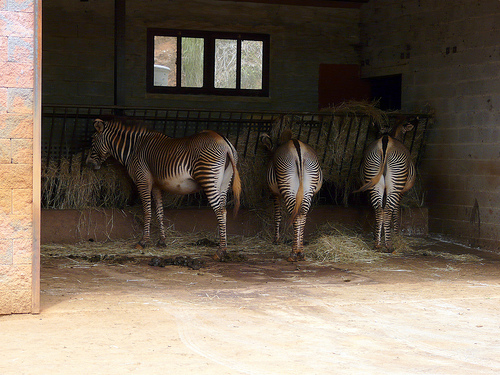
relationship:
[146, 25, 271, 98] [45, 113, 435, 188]
window over feeder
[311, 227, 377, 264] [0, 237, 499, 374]
hay on ground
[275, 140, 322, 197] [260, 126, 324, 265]
hind of zebra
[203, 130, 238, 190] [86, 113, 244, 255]
hind of zebra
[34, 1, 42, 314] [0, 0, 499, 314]
trim on wall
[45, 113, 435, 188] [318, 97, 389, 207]
feeder full of hay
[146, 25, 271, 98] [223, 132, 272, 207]
window above hay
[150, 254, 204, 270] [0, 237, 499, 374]
poo on ground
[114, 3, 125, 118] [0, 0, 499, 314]
beam on wall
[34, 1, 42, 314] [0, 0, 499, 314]
trim of wall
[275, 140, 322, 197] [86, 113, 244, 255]
hind of zebra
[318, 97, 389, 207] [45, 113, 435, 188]
hay in feeder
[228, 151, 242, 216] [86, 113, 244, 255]
tail of zebra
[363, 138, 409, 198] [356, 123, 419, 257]
hind of zebra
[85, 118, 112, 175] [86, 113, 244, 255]
head of zebra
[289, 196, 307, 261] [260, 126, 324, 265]
back legs of zebra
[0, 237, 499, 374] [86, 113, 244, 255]
ground under zebra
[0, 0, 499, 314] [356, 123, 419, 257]
wall beside zebra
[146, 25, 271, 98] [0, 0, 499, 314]
window on wall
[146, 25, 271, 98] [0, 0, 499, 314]
window on brick wall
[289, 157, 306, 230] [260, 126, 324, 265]
tail of zebra